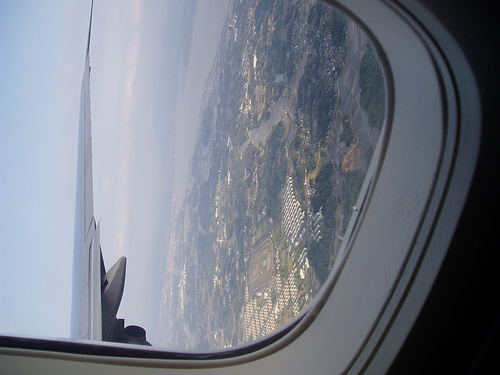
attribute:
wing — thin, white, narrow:
[70, 2, 104, 347]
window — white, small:
[0, 1, 486, 374]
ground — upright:
[154, 2, 385, 357]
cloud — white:
[114, 3, 143, 266]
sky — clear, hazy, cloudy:
[1, 1, 228, 346]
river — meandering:
[233, 81, 303, 171]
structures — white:
[228, 174, 307, 343]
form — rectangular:
[243, 231, 278, 296]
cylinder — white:
[124, 322, 147, 345]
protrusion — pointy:
[99, 254, 127, 323]